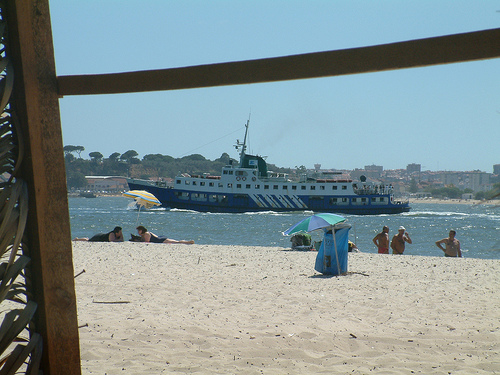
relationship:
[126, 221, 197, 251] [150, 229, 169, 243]
person wearing suit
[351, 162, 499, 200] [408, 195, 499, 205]
city near beach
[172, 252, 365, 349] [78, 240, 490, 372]
ground has sand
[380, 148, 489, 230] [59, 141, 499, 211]
buildings in background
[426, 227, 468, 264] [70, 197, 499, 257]
man standing near water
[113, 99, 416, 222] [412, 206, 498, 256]
cruise ship on water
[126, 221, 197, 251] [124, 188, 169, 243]
person under umbrella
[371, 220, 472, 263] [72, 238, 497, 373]
three men on beach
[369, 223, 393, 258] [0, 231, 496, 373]
man at beach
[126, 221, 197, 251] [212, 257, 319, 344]
person at beach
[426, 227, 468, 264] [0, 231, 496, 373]
man at beach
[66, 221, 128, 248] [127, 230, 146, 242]
person holding pillow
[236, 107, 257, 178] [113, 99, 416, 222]
mast on cruise ship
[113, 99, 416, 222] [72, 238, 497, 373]
cruise ship passing beach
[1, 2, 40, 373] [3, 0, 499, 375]
plant beside window frame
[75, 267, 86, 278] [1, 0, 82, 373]
nail in casing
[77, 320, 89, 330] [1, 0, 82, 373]
nail in casing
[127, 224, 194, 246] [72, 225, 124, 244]
person face to face with person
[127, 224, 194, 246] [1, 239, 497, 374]
person in sand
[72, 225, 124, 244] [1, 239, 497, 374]
person in sand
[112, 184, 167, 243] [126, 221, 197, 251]
umbrella shading person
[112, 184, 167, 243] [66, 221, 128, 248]
umbrella shading person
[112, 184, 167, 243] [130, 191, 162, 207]
umbrella with piping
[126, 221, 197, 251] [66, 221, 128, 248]
person talking to person